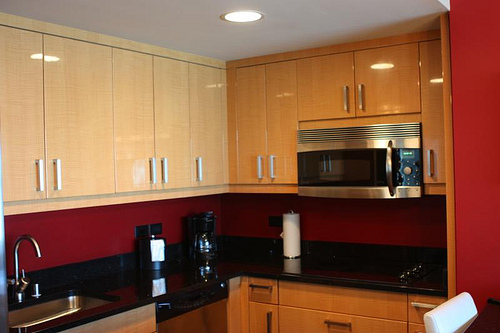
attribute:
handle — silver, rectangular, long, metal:
[147, 155, 156, 186]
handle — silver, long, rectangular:
[195, 154, 204, 183]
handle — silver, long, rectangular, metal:
[53, 156, 64, 194]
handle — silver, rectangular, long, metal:
[158, 155, 169, 186]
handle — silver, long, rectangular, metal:
[34, 155, 45, 195]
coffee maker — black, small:
[179, 207, 219, 261]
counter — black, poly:
[7, 234, 446, 333]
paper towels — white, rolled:
[280, 212, 302, 257]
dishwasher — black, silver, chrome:
[154, 278, 228, 331]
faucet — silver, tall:
[13, 230, 41, 303]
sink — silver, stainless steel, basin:
[5, 293, 113, 327]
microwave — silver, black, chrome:
[294, 121, 421, 199]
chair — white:
[422, 289, 477, 332]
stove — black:
[281, 252, 439, 284]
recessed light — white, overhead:
[222, 7, 261, 23]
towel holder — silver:
[283, 208, 302, 259]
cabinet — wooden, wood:
[112, 47, 191, 196]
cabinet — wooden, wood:
[1, 25, 116, 205]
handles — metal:
[146, 152, 170, 187]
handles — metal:
[36, 155, 62, 194]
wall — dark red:
[4, 191, 445, 281]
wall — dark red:
[448, 0, 499, 316]